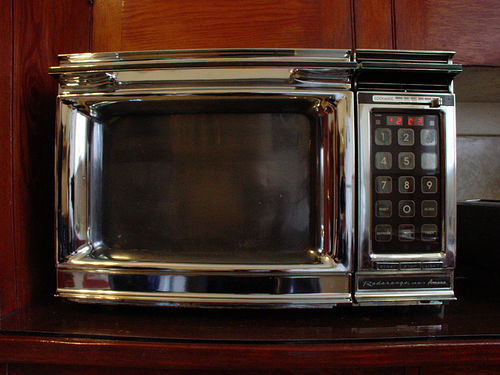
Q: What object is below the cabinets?
A: A microwave.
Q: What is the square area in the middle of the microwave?
A: A window.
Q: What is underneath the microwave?
A: A flat glass.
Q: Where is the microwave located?
A: Below the cabinet?.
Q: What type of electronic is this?
A: A microwave.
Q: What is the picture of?
A: A microwave oven.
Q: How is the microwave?
A: Metallic silver.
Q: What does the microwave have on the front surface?
A: A glass window.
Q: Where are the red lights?
A: On the control panel.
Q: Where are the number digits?
A: On the control panel.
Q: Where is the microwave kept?
A: On a shelf.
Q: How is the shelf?
A: A brown wooden shelf.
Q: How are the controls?
A: Digital.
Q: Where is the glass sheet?
A: On the shelf under the microwave.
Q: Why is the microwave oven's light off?
A: Not running.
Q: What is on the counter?
A: Silver microwave.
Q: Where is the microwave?
A: Countertop.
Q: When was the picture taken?
A: 12:02.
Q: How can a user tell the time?
A: LED display.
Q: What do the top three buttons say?
A: 1, 2, 3.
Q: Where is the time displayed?
A: Top right of microwave.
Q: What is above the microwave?
A: Wooden cabinets.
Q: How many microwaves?
A: 1.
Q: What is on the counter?
A: Microwave.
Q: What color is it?
A: Silver.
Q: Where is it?
A: On the counter.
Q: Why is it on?
A: To use.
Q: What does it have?
A: Buttons.